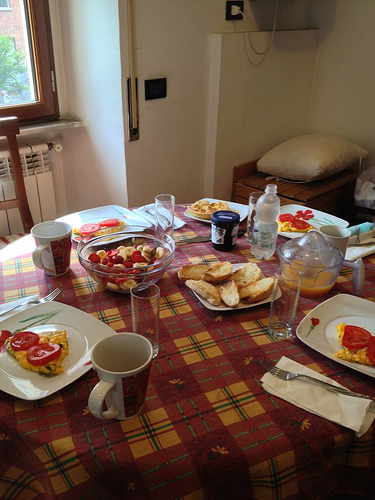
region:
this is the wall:
[150, 7, 190, 42]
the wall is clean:
[145, 10, 195, 56]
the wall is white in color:
[144, 9, 189, 48]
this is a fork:
[255, 350, 373, 421]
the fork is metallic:
[255, 348, 373, 406]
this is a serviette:
[305, 387, 326, 404]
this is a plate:
[11, 365, 26, 384]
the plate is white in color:
[81, 324, 100, 341]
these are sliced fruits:
[90, 240, 156, 268]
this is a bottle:
[255, 185, 281, 258]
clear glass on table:
[121, 279, 176, 343]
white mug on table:
[77, 345, 163, 431]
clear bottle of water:
[255, 166, 286, 260]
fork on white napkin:
[256, 351, 356, 421]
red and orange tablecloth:
[133, 319, 279, 459]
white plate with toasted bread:
[169, 261, 286, 311]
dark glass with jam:
[204, 211, 238, 262]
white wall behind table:
[176, 48, 222, 124]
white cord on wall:
[226, 0, 288, 69]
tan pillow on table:
[247, 96, 353, 192]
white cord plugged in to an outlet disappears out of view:
[222, 0, 283, 55]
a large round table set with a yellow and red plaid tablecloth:
[0, 203, 373, 498]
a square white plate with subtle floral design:
[1, 299, 116, 401]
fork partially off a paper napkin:
[259, 353, 373, 438]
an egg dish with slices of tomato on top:
[3, 326, 68, 376]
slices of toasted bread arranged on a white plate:
[175, 257, 280, 312]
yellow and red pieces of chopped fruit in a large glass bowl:
[77, 225, 173, 292]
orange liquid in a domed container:
[275, 230, 363, 293]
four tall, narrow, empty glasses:
[130, 192, 303, 358]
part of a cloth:
[242, 417, 271, 452]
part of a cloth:
[212, 409, 233, 441]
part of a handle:
[92, 387, 118, 447]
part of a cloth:
[230, 387, 252, 419]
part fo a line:
[238, 396, 256, 428]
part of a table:
[220, 405, 245, 446]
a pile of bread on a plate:
[175, 256, 280, 314]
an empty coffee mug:
[81, 332, 159, 425]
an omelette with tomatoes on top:
[0, 324, 75, 385]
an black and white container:
[207, 207, 243, 250]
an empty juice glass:
[124, 281, 164, 360]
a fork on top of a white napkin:
[259, 353, 371, 436]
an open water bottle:
[247, 178, 282, 260]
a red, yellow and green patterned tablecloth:
[0, 189, 373, 493]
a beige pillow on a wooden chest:
[253, 126, 370, 191]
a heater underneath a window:
[1, 139, 67, 242]